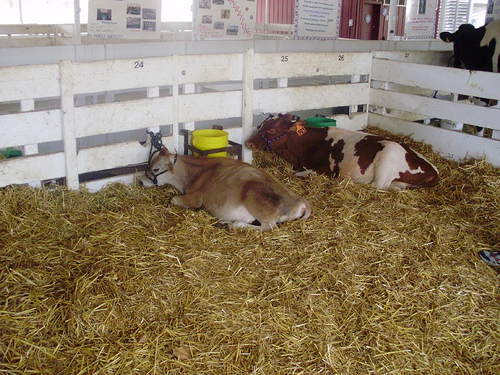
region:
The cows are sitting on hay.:
[0, 42, 488, 372]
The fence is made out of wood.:
[1, 52, 372, 188]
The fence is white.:
[368, 50, 498, 190]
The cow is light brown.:
[130, 142, 310, 232]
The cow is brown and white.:
[237, 98, 437, 199]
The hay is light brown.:
[91, 282, 462, 352]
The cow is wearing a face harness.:
[130, 146, 180, 191]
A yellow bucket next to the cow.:
[180, 110, 235, 155]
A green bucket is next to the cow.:
[301, 110, 341, 127]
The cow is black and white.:
[429, 10, 499, 72]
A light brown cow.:
[139, 145, 314, 236]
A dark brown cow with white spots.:
[254, 112, 445, 191]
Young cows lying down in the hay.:
[127, 108, 448, 235]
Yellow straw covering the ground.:
[0, 120, 499, 373]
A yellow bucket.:
[191, 130, 228, 157]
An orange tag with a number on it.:
[295, 122, 306, 137]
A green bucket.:
[302, 115, 339, 127]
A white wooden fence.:
[0, 48, 497, 196]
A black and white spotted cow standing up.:
[437, 12, 497, 137]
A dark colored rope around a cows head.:
[146, 127, 178, 186]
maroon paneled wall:
[254, 0, 408, 41]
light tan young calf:
[133, 144, 310, 237]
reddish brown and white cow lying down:
[244, 110, 441, 190]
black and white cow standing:
[438, 17, 498, 138]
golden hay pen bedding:
[0, 122, 499, 374]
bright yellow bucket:
[191, 128, 231, 159]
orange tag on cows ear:
[295, 123, 307, 136]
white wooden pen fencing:
[0, 20, 499, 200]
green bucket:
[303, 115, 339, 127]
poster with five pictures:
[84, 0, 161, 42]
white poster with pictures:
[85, 1, 164, 43]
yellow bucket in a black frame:
[178, 124, 245, 164]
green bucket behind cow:
[301, 114, 338, 132]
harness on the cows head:
[129, 134, 183, 198]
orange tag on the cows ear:
[290, 120, 312, 141]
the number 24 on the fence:
[131, 56, 148, 72]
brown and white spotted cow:
[236, 107, 445, 197]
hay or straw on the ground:
[144, 261, 411, 351]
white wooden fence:
[5, 19, 497, 190]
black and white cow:
[433, 16, 498, 161]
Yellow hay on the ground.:
[329, 230, 434, 348]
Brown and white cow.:
[254, 94, 436, 196]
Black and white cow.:
[437, 13, 498, 58]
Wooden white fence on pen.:
[40, 52, 146, 197]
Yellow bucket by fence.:
[190, 118, 232, 157]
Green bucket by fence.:
[302, 109, 340, 126]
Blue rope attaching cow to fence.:
[138, 125, 191, 204]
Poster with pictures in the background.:
[85, 0, 163, 40]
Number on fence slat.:
[124, 54, 163, 93]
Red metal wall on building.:
[257, 0, 289, 42]